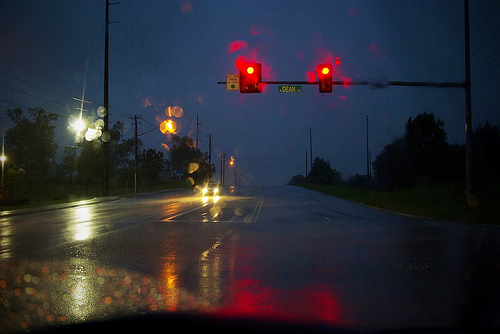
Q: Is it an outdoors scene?
A: Yes, it is outdoors.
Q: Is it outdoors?
A: Yes, it is outdoors.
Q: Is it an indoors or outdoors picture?
A: It is outdoors.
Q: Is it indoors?
A: No, it is outdoors.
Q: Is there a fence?
A: No, there are no fences.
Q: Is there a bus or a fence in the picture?
A: No, there are no fences or buses.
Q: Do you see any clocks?
A: No, there are no clocks.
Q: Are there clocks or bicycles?
A: No, there are no clocks or bicycles.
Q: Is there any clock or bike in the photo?
A: No, there are no clocks or bikes.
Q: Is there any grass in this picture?
A: Yes, there is grass.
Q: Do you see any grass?
A: Yes, there is grass.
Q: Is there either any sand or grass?
A: Yes, there is grass.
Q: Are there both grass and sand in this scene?
A: No, there is grass but no sand.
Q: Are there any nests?
A: No, there are no nests.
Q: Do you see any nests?
A: No, there are no nests.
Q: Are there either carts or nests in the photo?
A: No, there are no nests or carts.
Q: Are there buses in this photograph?
A: No, there are no buses.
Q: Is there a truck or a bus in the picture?
A: No, there are no buses or trucks.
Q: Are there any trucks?
A: No, there are no trucks.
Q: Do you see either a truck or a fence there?
A: No, there are no trucks or fences.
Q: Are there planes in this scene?
A: No, there are no planes.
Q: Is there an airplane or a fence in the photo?
A: No, there are no airplanes or fences.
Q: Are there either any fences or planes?
A: No, there are no planes or fences.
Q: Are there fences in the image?
A: No, there are no fences.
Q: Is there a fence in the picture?
A: No, there are no fences.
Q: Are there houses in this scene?
A: No, there are no houses.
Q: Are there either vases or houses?
A: No, there are no houses or vases.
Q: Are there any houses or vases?
A: No, there are no houses or vases.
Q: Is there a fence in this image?
A: No, there are no fences.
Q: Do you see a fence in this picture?
A: No, there are no fences.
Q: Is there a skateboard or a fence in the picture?
A: No, there are no fences or skateboards.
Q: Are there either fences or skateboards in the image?
A: No, there are no fences or skateboards.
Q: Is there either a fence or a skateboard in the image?
A: No, there are no fences or skateboards.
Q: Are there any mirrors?
A: No, there are no mirrors.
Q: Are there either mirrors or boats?
A: No, there are no mirrors or boats.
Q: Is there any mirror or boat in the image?
A: No, there are no mirrors or boats.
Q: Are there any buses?
A: No, there are no buses.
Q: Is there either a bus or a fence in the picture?
A: No, there are no buses or fences.